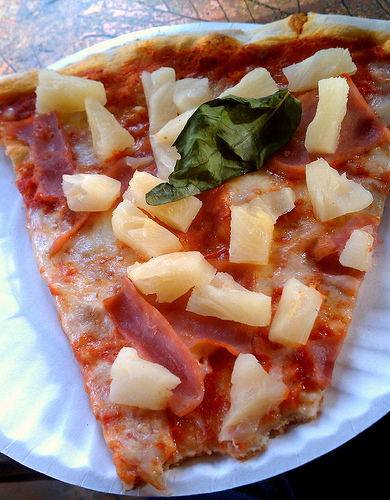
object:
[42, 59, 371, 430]
pineapple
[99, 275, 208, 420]
bacon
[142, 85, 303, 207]
leaf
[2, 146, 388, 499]
paper plate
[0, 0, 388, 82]
crust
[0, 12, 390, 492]
melted cheese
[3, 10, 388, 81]
countertop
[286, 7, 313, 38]
spot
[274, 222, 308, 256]
oily spot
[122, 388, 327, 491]
bite mark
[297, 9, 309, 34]
crack